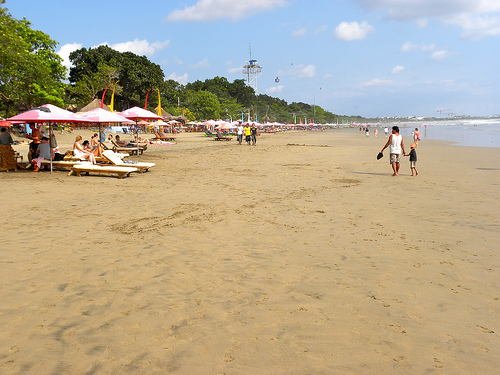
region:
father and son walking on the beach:
[366, 123, 426, 185]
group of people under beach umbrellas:
[15, 94, 167, 185]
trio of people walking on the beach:
[229, 121, 264, 151]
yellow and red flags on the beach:
[84, 70, 180, 143]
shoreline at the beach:
[343, 113, 498, 161]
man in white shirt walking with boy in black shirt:
[368, 118, 431, 181]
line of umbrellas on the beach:
[161, 101, 353, 145]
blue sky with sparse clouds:
[318, 1, 497, 105]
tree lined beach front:
[3, 8, 373, 186]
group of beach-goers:
[340, 103, 387, 143]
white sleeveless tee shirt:
[389, 133, 403, 154]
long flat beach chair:
[71, 159, 134, 179]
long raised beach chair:
[102, 148, 154, 169]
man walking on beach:
[378, 121, 405, 177]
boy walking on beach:
[405, 143, 419, 176]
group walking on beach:
[231, 123, 259, 143]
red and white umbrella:
[5, 100, 82, 121]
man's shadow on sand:
[351, 168, 393, 178]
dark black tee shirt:
[409, 148, 416, 162]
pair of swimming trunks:
[390, 152, 401, 162]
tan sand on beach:
[41, 203, 65, 225]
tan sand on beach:
[143, 244, 198, 298]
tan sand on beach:
[196, 282, 231, 328]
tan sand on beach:
[287, 231, 332, 279]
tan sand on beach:
[331, 272, 366, 322]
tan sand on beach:
[370, 288, 433, 330]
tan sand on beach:
[410, 231, 452, 267]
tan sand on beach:
[420, 195, 470, 234]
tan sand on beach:
[301, 123, 333, 155]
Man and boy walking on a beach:
[375, 123, 419, 178]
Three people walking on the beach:
[232, 119, 263, 148]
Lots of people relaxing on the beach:
[0, 102, 498, 184]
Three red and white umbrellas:
[5, 100, 162, 125]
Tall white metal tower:
[237, 38, 264, 93]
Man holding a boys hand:
[376, 125, 420, 179]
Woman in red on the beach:
[410, 124, 422, 144]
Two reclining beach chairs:
[202, 125, 233, 142]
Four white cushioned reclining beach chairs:
[28, 146, 158, 178]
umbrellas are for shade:
[11, 103, 164, 126]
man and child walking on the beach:
[376, 124, 417, 176]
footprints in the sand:
[117, 204, 216, 239]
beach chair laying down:
[73, 161, 138, 174]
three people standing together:
[233, 121, 260, 142]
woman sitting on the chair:
[69, 137, 96, 163]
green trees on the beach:
[0, 8, 330, 120]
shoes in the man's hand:
[376, 152, 383, 159]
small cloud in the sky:
[335, 20, 372, 42]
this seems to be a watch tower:
[238, 40, 264, 125]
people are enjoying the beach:
[0, 101, 433, 186]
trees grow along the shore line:
[3, 3, 499, 130]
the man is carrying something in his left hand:
[375, 149, 385, 162]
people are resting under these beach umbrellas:
[11, 98, 163, 178]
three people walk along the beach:
[231, 119, 261, 146]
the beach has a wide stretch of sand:
[0, 126, 499, 373]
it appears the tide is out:
[373, 116, 498, 156]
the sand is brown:
[279, 297, 352, 346]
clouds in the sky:
[335, 21, 369, 40]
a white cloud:
[333, 20, 368, 40]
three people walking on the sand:
[383, 123, 421, 174]